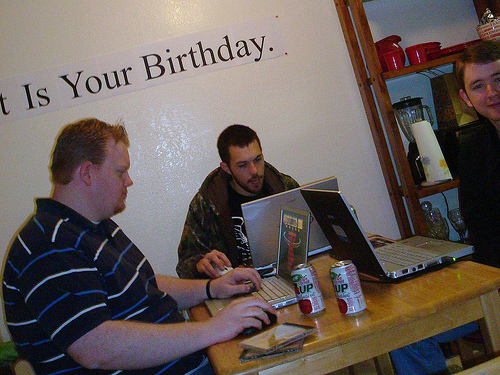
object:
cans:
[327, 261, 365, 315]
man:
[0, 115, 279, 374]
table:
[191, 236, 498, 374]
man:
[387, 42, 500, 375]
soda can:
[290, 264, 326, 317]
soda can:
[328, 258, 366, 316]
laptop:
[297, 187, 474, 287]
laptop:
[239, 176, 346, 280]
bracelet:
[204, 278, 213, 301]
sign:
[0, 22, 283, 124]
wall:
[0, 0, 410, 344]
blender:
[392, 94, 435, 183]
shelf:
[336, 0, 499, 250]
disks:
[240, 322, 317, 364]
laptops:
[202, 209, 313, 320]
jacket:
[174, 160, 299, 280]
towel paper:
[405, 119, 451, 186]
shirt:
[3, 199, 213, 374]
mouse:
[240, 312, 275, 338]